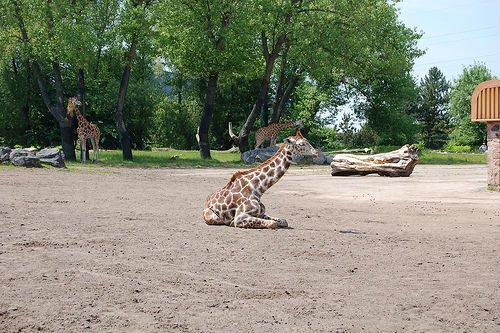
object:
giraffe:
[202, 128, 319, 229]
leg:
[232, 212, 279, 230]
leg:
[263, 214, 288, 227]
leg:
[270, 135, 274, 146]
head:
[283, 128, 318, 157]